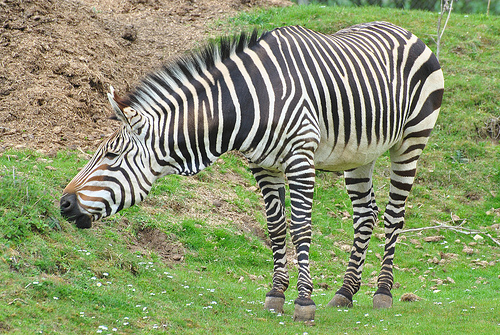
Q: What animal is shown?
A: Zebra.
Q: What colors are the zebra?
A: Black, white.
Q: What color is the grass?
A: Green.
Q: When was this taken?
A: Daytime.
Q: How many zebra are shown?
A: 1.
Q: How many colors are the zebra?
A: 2.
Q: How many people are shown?
A: 0.